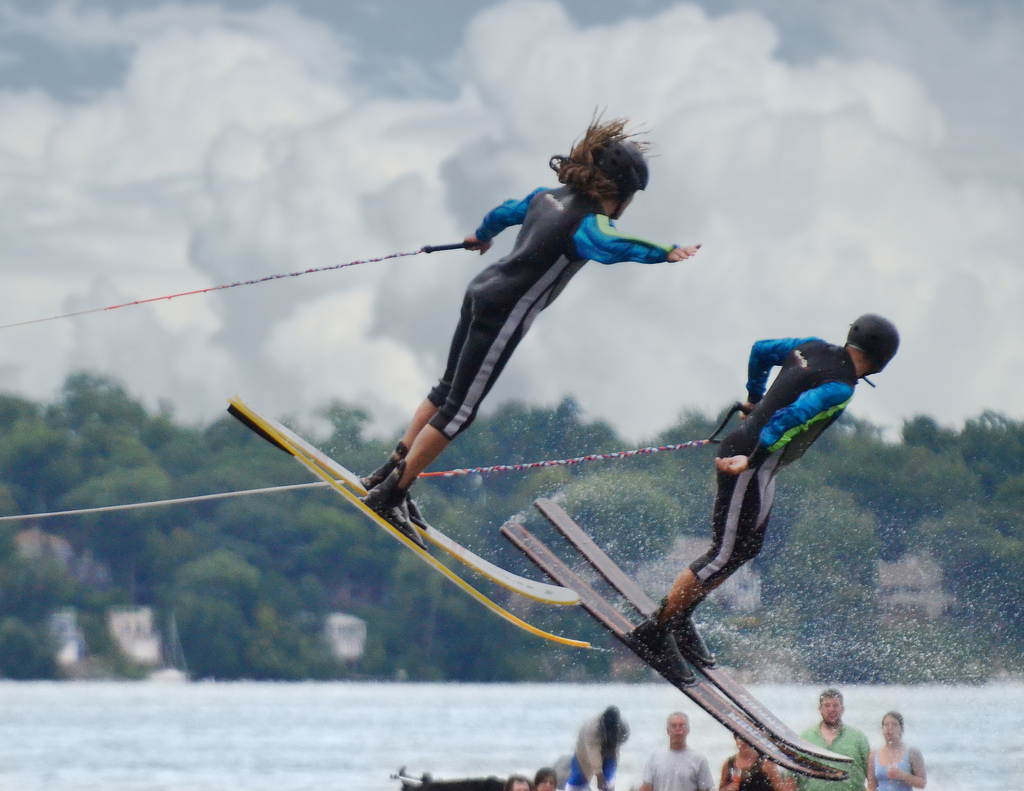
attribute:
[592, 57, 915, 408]
helmets — black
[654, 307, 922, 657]
suit — wet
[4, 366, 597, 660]
skiis — water skis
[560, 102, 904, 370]
helmets — black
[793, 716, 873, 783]
shirt — green